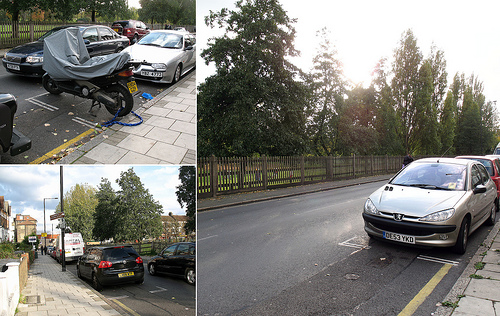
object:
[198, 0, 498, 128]
sky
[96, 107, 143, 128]
cord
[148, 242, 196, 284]
parkedcars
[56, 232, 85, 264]
parkedcars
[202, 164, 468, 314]
street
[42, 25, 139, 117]
motorcycle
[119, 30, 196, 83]
car.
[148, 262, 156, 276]
wheel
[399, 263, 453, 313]
line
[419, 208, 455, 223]
headlight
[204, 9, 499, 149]
trees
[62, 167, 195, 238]
trees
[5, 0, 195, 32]
trees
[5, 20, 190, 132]
road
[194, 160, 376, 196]
grass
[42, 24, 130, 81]
cover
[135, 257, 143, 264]
taillight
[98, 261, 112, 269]
taillight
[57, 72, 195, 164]
sidewalk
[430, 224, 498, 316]
sidewalk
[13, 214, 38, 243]
building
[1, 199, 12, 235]
building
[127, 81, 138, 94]
plate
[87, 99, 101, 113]
kickstand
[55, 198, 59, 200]
light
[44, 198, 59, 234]
pole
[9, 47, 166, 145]
street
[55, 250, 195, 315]
street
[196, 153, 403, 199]
fence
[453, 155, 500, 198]
car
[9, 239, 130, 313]
sidewalk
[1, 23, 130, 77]
black car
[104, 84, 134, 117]
tire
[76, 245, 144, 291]
cars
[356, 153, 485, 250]
car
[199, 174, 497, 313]
road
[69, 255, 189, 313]
road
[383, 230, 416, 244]
license plate